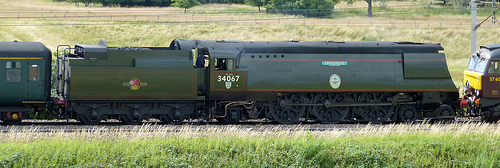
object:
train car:
[55, 39, 461, 127]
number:
[217, 75, 239, 82]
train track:
[2, 125, 499, 130]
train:
[0, 39, 500, 125]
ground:
[0, 21, 499, 167]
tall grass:
[3, 125, 498, 167]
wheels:
[4, 113, 23, 124]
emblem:
[122, 78, 147, 91]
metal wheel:
[262, 92, 456, 125]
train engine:
[195, 39, 458, 102]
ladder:
[55, 45, 65, 97]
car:
[0, 40, 499, 125]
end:
[55, 44, 92, 100]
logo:
[122, 78, 149, 91]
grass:
[0, 132, 497, 168]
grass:
[3, 3, 500, 47]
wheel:
[355, 94, 395, 124]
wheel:
[264, 92, 308, 125]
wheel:
[311, 93, 352, 123]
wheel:
[397, 103, 419, 123]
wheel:
[434, 105, 455, 124]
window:
[2, 61, 23, 82]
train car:
[54, 40, 206, 105]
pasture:
[2, 5, 491, 51]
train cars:
[0, 41, 53, 125]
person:
[215, 60, 228, 70]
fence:
[2, 2, 498, 27]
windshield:
[466, 58, 487, 72]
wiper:
[476, 57, 485, 64]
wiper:
[470, 55, 476, 60]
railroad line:
[1, 112, 495, 129]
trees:
[254, 0, 338, 18]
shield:
[225, 82, 233, 90]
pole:
[468, 1, 478, 53]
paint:
[463, 69, 481, 91]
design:
[329, 73, 342, 89]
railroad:
[7, 39, 484, 123]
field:
[0, 26, 499, 168]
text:
[321, 61, 348, 67]